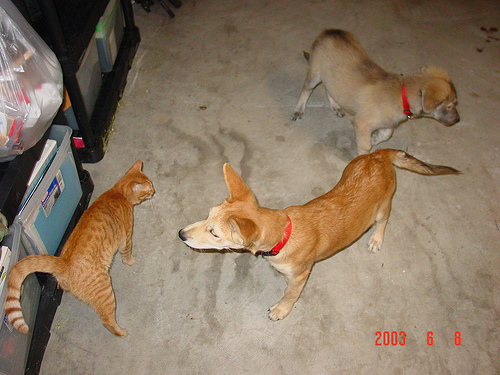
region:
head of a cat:
[111, 153, 196, 213]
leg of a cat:
[110, 224, 168, 270]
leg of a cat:
[96, 282, 119, 349]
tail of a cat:
[0, 264, 69, 324]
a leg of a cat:
[94, 292, 137, 347]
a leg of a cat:
[110, 239, 138, 273]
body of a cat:
[48, 205, 148, 307]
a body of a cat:
[43, 184, 145, 296]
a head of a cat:
[118, 150, 170, 215]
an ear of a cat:
[126, 160, 148, 181]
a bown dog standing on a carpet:
[293, 28, 460, 156]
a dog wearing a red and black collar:
[258, 210, 293, 261]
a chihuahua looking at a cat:
[176, 150, 463, 322]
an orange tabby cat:
[5, 161, 157, 336]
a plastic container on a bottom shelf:
[18, 123, 83, 255]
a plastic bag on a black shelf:
[0, 0, 64, 162]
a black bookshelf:
[16, 0, 140, 163]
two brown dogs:
[178, 28, 460, 321]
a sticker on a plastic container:
[41, 168, 64, 218]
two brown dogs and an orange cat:
[6, 24, 461, 338]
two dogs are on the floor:
[180, 40, 495, 342]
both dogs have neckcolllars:
[186, 78, 485, 279]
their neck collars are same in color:
[165, 59, 440, 271]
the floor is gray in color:
[166, 281, 266, 373]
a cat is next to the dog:
[29, 146, 211, 328]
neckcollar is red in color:
[244, 191, 314, 322]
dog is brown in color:
[222, 177, 493, 299]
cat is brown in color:
[58, 208, 147, 335]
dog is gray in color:
[303, 30, 478, 170]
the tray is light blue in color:
[21, 144, 96, 241]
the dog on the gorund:
[178, 146, 460, 326]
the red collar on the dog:
[270, 208, 295, 263]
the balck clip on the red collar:
[253, 248, 275, 258]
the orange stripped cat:
[65, 156, 158, 348]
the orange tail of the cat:
[0, 253, 73, 335]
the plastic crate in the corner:
[0, 133, 85, 222]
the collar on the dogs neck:
[393, 70, 420, 120]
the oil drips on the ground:
[468, 10, 498, 60]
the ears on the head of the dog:
[220, 158, 262, 249]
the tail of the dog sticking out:
[390, 145, 468, 186]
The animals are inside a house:
[21, 21, 497, 322]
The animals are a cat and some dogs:
[28, 16, 498, 356]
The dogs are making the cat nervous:
[25, 21, 491, 341]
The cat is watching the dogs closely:
[22, 33, 485, 360]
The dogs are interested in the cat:
[25, 21, 480, 336]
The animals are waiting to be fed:
[42, 25, 489, 366]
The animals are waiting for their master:
[20, 13, 465, 373]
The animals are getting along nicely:
[46, 22, 493, 365]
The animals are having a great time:
[47, 13, 482, 360]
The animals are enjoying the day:
[27, 20, 478, 355]